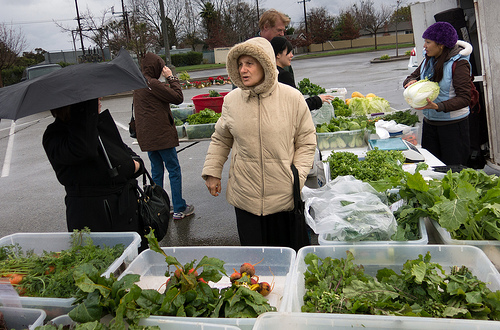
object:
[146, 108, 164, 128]
brown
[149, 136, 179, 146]
color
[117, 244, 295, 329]
bucket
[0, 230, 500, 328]
stand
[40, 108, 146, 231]
black jacket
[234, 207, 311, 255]
pants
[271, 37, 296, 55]
black hair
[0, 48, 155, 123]
umbrella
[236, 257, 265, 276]
radish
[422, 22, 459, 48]
cap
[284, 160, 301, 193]
pocket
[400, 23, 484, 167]
woman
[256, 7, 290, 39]
man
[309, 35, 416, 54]
fence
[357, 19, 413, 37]
house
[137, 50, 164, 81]
hood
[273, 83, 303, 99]
shoulder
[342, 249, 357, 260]
leaves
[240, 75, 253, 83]
mouth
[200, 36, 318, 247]
woman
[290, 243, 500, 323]
bins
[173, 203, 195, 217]
sneaker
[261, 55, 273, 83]
fur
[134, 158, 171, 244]
bags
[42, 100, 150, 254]
woman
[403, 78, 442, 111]
fruits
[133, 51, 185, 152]
brown jacket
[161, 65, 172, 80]
hand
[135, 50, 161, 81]
head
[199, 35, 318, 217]
jacket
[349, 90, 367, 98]
vegetable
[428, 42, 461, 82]
hair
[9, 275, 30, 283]
carrots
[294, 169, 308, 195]
hand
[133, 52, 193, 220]
woman